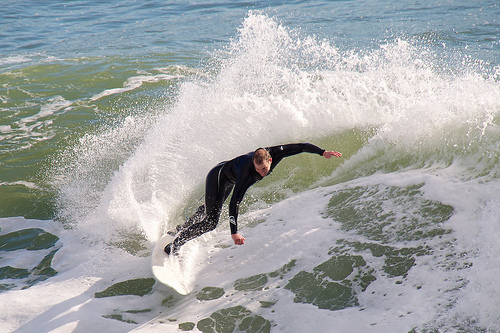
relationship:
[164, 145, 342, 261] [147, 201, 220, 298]
man on a surfboard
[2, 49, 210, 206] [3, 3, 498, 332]
waves in water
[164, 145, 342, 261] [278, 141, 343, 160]
man raises arm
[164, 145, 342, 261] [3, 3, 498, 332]
man in water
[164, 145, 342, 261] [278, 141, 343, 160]
man stretches an arm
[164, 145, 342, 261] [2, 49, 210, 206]
man near a waves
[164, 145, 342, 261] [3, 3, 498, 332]
man looks down at water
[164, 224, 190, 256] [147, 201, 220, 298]
feet on surfboard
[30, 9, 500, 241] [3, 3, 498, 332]
spray of water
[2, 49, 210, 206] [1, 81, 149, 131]
waves on bottom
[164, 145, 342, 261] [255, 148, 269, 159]
man with a bald spot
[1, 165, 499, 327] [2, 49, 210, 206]
foam by waves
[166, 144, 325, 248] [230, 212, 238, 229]
wet suit has writing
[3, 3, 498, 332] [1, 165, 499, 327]
water with foam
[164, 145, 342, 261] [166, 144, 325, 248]
man in a wet suit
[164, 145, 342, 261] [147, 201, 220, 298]
man rides a surfboard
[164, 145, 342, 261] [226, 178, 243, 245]
man extendes h arm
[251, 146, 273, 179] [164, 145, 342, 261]
head of a man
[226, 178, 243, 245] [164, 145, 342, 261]
arm of man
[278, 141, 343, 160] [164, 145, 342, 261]
arm of man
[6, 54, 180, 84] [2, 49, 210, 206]
crest of a waves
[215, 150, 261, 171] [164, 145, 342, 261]
back of a man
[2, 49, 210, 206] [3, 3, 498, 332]
waves on water